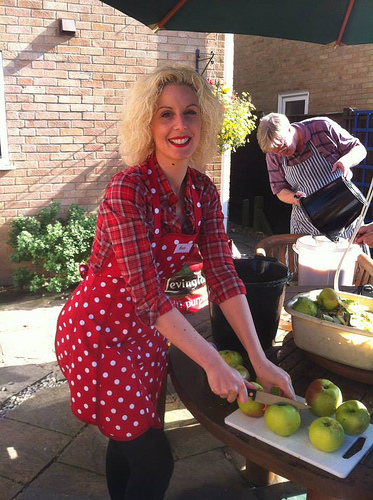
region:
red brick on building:
[4, 5, 31, 15]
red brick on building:
[31, 9, 55, 18]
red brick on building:
[56, 10, 79, 20]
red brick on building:
[80, 11, 103, 21]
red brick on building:
[101, 12, 124, 24]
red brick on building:
[6, 26, 32, 32]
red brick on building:
[31, 26, 52, 35]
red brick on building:
[80, 29, 103, 37]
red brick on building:
[101, 30, 124, 39]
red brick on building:
[49, 135, 72, 143]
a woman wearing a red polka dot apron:
[55, 65, 297, 498]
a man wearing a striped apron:
[257, 112, 367, 234]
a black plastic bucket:
[297, 176, 364, 235]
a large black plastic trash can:
[207, 255, 287, 361]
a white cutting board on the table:
[224, 393, 372, 475]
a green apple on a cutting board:
[263, 401, 300, 435]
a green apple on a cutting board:
[308, 417, 343, 451]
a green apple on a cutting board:
[336, 399, 369, 435]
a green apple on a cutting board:
[305, 379, 342, 415]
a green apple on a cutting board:
[237, 381, 265, 416]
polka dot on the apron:
[124, 311, 135, 321]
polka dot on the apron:
[120, 383, 132, 393]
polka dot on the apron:
[137, 405, 148, 416]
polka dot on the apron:
[121, 414, 128, 420]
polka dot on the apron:
[125, 430, 136, 441]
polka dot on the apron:
[100, 385, 113, 395]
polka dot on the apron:
[98, 367, 109, 381]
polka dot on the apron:
[102, 326, 115, 335]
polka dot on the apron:
[119, 327, 130, 336]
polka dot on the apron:
[98, 306, 107, 317]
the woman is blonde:
[73, 57, 247, 277]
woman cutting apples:
[38, 56, 371, 469]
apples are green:
[238, 359, 364, 461]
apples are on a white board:
[218, 362, 371, 493]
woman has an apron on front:
[42, 58, 297, 486]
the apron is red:
[56, 157, 206, 447]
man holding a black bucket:
[251, 101, 371, 262]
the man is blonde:
[247, 103, 344, 198]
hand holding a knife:
[198, 351, 317, 418]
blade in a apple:
[245, 381, 313, 436]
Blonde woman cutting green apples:
[54, 65, 303, 498]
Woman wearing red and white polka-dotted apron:
[53, 64, 303, 498]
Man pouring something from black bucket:
[256, 110, 371, 279]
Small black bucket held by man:
[298, 174, 368, 244]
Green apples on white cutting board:
[223, 376, 372, 479]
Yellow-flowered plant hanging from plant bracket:
[193, 47, 257, 155]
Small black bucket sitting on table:
[205, 253, 295, 357]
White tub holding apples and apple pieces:
[284, 287, 371, 370]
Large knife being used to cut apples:
[235, 386, 311, 411]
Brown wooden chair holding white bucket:
[254, 231, 371, 288]